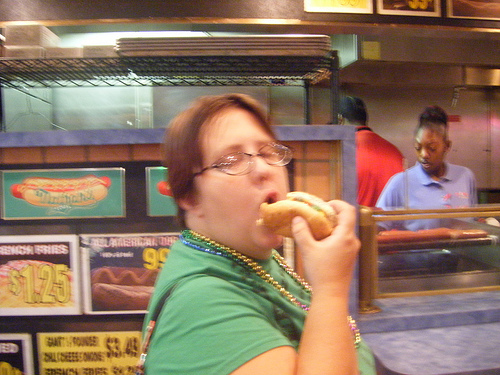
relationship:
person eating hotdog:
[127, 84, 396, 374] [259, 182, 342, 239]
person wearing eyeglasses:
[127, 84, 396, 374] [206, 140, 292, 176]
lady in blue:
[365, 104, 485, 219] [373, 165, 484, 221]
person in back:
[341, 94, 406, 208] [337, 86, 499, 111]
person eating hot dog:
[127, 84, 396, 374] [259, 182, 342, 239]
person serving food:
[365, 104, 485, 219] [376, 224, 500, 245]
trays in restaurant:
[115, 27, 338, 60] [4, 4, 500, 375]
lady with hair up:
[365, 104, 485, 219] [408, 102, 456, 136]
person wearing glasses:
[127, 84, 396, 374] [206, 140, 292, 176]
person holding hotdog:
[127, 84, 396, 374] [259, 182, 342, 239]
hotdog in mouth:
[259, 182, 342, 239] [258, 185, 287, 208]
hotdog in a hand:
[259, 182, 342, 239] [290, 197, 372, 304]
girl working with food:
[365, 104, 485, 219] [376, 224, 500, 245]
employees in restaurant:
[365, 104, 485, 219] [4, 4, 500, 375]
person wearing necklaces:
[127, 84, 396, 374] [180, 219, 368, 348]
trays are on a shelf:
[115, 27, 338, 60] [4, 58, 355, 116]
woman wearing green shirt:
[127, 84, 396, 374] [130, 234, 381, 374]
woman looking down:
[365, 104, 485, 219] [363, 247, 499, 292]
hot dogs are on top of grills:
[376, 224, 500, 245] [379, 236, 499, 257]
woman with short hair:
[127, 84, 396, 374] [136, 87, 316, 248]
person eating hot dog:
[127, 84, 396, 374] [206, 140, 292, 176]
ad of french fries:
[1, 236, 85, 319] [1, 242, 73, 306]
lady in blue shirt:
[365, 104, 485, 219] [373, 165, 484, 221]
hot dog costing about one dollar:
[79, 230, 165, 313] [142, 246, 166, 273]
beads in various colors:
[180, 219, 368, 348] [176, 227, 309, 328]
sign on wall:
[6, 171, 118, 215] [1, 140, 341, 373]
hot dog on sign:
[12, 174, 110, 205] [6, 171, 118, 215]